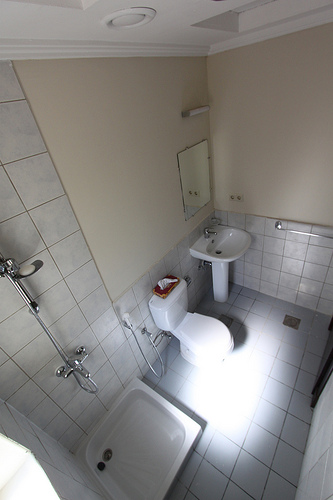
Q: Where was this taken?
A: A bathroom.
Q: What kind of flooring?
A: Tiles.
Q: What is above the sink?
A: A mirror.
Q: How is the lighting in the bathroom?
A: Bright.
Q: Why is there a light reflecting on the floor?
A: Ceiling lamp is on.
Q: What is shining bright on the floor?
A: Light fixture on the ceiling.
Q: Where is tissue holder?
A: On top of the toilet tank.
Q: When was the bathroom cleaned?
A: After working hours.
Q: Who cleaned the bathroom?
A: Cleaning crew.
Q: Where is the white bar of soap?
A: In the shower.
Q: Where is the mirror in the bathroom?
A: On the wall above the white sink.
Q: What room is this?
A: A bathroom.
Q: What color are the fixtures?
A: White.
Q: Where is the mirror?
A: Hanging above the sink.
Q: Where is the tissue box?
A: On the toilet tank.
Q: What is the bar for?
A: Hanging towels.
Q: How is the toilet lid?
A: Closed.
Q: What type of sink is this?
A: Pedestal.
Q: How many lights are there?
A: One.